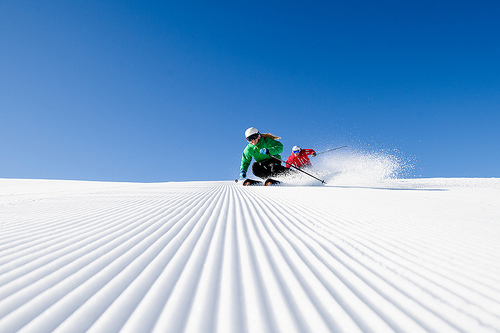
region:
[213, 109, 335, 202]
The people are skiing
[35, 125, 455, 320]
The snow has ridges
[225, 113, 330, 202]
Woman wearing a green jacket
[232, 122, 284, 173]
Woman wearing white helmet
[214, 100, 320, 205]
Woman holding ski poles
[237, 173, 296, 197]
The skis are black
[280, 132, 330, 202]
Person wearing a red jacket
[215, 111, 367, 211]
People skiing down a mountain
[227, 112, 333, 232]
Woman wearing black pants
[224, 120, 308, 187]
Woman with long brown hair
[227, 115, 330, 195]
Two people skiing.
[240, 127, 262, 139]
A person wearing a white helmet.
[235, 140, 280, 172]
A person wearing a green coat.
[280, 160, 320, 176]
A ski pole.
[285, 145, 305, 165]
A person wearng a red coat.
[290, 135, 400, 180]
Snow being kicked up by the skier.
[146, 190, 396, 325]
Groves formed in the snow.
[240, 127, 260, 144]
A person wearing dark sunglasses.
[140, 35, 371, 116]
A bright blue sky.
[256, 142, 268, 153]
Person wearing blue gloves.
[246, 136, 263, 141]
Black sketting sun glasses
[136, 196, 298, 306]
staight Snow sketting trails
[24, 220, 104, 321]
staight Snow sketting trails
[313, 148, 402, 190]
Snow dust raising to the sky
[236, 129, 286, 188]
A man sketting on snow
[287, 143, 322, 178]
A man sketting on snow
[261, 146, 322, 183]
a sketting balancing stick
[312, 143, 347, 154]
a sketting balancing stick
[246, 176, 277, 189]
Big Black sketting shoes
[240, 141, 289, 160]
Green heavy sketting jacket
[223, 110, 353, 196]
Two skiers in the snow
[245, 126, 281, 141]
The woman's hair is long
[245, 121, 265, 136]
A white helmet on the woman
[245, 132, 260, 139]
Goggles on the woman's face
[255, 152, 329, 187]
A skipole in the woman's hand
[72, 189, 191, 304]
Neat lines in the snow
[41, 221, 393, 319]
Thick snow on the ground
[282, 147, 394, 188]
A flurry of snow being kicked up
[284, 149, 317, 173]
A skier in a red jacket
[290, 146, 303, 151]
A white helmet on the man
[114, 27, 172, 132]
part of the sky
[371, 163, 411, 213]
part of a splash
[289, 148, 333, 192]
part of a hooker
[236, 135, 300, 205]
part of a board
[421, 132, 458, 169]
part of the sky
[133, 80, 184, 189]
part of the sky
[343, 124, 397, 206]
part of a splash